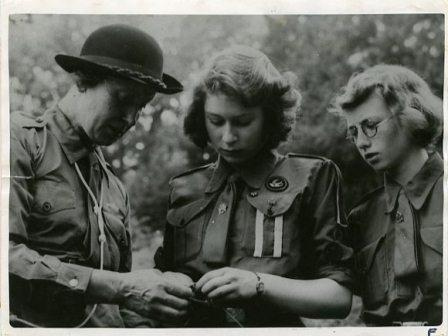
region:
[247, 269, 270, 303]
A wristwatch on a wrist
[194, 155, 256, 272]
A tied tie on a person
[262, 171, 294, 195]
The girls scout badge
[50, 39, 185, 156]
A funny looking hat on a funny looking woman's head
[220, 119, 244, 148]
a nose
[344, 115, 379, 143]
Glasses on a girl's face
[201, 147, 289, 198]
The collar of a shirt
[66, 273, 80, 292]
The button on a sleeve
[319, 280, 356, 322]
The girl's elbow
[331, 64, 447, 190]
The head of a girl scout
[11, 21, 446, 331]
three girl scouts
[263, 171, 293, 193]
badge on front of shirt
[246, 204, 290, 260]
stripes on front shirt pocket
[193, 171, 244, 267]
short tie on front of shirt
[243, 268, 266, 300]
watch on wrist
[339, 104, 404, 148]
pair of eye glasses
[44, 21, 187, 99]
black hat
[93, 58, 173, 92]
black cord on top of black hat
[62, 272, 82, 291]
white button on cuff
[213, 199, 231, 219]
pin on tie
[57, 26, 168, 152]
head of a person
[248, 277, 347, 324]
arm of a person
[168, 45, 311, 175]
head of a person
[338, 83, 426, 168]
head of a person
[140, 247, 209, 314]
hand of a person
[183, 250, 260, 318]
hand of a person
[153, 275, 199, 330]
finger of a person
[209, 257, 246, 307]
fingers of a person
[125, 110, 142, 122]
nose of a person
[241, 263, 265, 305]
Woman wearing a watch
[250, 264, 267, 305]
Woman is wearing a watch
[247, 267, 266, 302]
Woman wearing a wrist watch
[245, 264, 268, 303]
Woman is wearing a wrist watch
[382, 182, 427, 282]
Woman wearing a tie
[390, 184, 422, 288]
Woman is wearing a tie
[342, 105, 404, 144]
Woman wearing glasses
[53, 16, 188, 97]
Woman wearing a hat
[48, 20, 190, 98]
Woman is wearing a hat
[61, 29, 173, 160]
head of a person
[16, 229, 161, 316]
arm of a person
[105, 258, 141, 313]
wrist of a person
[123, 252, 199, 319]
hand of a person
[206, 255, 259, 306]
hand of a person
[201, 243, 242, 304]
finger of a person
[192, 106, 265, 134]
eye of a person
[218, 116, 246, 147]
nose of a person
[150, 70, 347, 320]
woman looking at something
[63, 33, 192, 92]
trilby hat on woman's head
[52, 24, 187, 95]
Dark hat on a man talking to a woman.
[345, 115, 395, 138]
Glasses on a blonde woman's face.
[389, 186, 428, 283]
Tie on a light haired woman's shirt.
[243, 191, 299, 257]
Pocket with two white stripes on a uniform.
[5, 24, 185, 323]
Man in a hat talking to two women.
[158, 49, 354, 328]
Brown haired woman looking down.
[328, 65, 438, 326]
Light haired woman to the right.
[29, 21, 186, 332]
a woman standing outside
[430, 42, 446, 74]
leaves on the tree